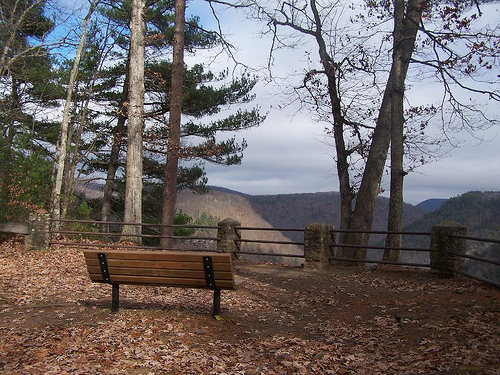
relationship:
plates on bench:
[96, 248, 223, 285] [76, 240, 251, 319]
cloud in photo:
[262, 127, 333, 187] [6, 8, 484, 357]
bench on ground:
[83, 251, 236, 314] [9, 247, 497, 373]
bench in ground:
[83, 251, 236, 314] [0, 256, 437, 366]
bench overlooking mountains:
[80, 251, 236, 322] [62, 167, 499, 289]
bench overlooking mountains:
[80, 251, 236, 322] [232, 180, 482, 241]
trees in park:
[1, 0, 498, 263] [1, 2, 496, 371]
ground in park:
[253, 263, 437, 367] [8, 185, 484, 373]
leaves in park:
[276, 278, 406, 365] [8, 185, 484, 373]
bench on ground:
[67, 236, 273, 338] [295, 218, 425, 350]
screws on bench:
[100, 250, 105, 272] [71, 241, 259, 302]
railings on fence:
[242, 222, 304, 234] [152, 220, 435, 260]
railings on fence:
[249, 236, 301, 248] [152, 220, 435, 260]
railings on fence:
[240, 248, 302, 262] [152, 220, 435, 260]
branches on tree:
[169, 61, 268, 199] [0, 1, 257, 246]